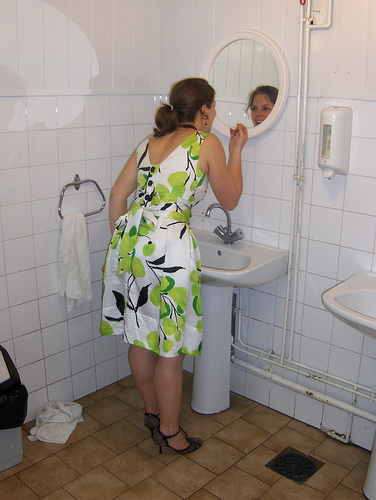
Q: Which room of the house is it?
A: It is a bathroom.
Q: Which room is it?
A: It is a bathroom.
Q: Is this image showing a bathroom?
A: Yes, it is showing a bathroom.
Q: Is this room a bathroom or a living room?
A: It is a bathroom.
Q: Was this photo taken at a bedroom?
A: No, the picture was taken in a bathroom.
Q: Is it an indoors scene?
A: Yes, it is indoors.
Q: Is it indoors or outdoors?
A: It is indoors.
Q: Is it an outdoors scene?
A: No, it is indoors.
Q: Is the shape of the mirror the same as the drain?
A: No, the mirror is round and the drain is square.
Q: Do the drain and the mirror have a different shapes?
A: Yes, the drain is round and the mirror is square.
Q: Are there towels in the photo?
A: Yes, there is a towel.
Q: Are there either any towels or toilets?
A: Yes, there is a towel.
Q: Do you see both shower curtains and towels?
A: No, there is a towel but no shower curtains.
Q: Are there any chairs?
A: No, there are no chairs.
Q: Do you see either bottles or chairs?
A: No, there are no chairs or bottles.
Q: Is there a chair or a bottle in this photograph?
A: No, there are no chairs or bottles.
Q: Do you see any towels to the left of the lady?
A: Yes, there is a towel to the left of the lady.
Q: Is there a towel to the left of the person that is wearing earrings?
A: Yes, there is a towel to the left of the lady.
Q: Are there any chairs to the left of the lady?
A: No, there is a towel to the left of the lady.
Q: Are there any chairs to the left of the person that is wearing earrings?
A: No, there is a towel to the left of the lady.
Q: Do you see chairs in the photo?
A: No, there are no chairs.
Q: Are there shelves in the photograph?
A: No, there are no shelves.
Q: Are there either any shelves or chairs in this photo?
A: No, there are no shelves or chairs.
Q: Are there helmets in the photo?
A: No, there are no helmets.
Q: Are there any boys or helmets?
A: No, there are no helmets or boys.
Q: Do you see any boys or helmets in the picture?
A: No, there are no helmets or boys.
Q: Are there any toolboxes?
A: No, there are no toolboxes.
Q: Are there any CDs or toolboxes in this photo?
A: No, there are no toolboxes or cds.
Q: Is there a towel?
A: Yes, there is a towel.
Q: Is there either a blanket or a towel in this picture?
A: Yes, there is a towel.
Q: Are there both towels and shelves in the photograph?
A: No, there is a towel but no shelves.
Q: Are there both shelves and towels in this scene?
A: No, there is a towel but no shelves.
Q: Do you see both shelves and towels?
A: No, there is a towel but no shelves.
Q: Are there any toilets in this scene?
A: No, there are no toilets.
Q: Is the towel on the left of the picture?
A: Yes, the towel is on the left of the image.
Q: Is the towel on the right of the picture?
A: No, the towel is on the left of the image.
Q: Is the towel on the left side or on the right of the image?
A: The towel is on the left of the image.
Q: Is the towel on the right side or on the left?
A: The towel is on the left of the image.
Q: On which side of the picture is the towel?
A: The towel is on the left of the image.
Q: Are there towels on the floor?
A: Yes, there is a towel on the floor.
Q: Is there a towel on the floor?
A: Yes, there is a towel on the floor.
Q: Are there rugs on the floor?
A: No, there is a towel on the floor.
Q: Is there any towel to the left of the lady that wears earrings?
A: Yes, there is a towel to the left of the lady.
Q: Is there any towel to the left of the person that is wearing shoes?
A: Yes, there is a towel to the left of the lady.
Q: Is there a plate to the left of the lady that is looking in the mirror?
A: No, there is a towel to the left of the lady.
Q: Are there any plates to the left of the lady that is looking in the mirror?
A: No, there is a towel to the left of the lady.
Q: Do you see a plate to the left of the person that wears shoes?
A: No, there is a towel to the left of the lady.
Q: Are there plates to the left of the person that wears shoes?
A: No, there is a towel to the left of the lady.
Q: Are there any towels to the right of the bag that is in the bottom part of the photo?
A: Yes, there is a towel to the right of the handbag.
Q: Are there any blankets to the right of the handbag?
A: No, there is a towel to the right of the handbag.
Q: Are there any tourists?
A: No, there are no tourists.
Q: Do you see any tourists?
A: No, there are no tourists.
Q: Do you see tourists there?
A: No, there are no tourists.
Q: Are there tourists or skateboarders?
A: No, there are no tourists or skateboarders.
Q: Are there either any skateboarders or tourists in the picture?
A: No, there are no tourists or skateboarders.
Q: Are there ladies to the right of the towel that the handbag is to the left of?
A: Yes, there is a lady to the right of the towel.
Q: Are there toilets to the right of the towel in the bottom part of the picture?
A: No, there is a lady to the right of the towel.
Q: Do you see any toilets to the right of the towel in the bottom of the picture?
A: No, there is a lady to the right of the towel.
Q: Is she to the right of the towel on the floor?
A: Yes, the lady is to the right of the towel.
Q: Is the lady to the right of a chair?
A: No, the lady is to the right of the towel.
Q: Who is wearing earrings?
A: The lady is wearing earrings.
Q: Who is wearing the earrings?
A: The lady is wearing earrings.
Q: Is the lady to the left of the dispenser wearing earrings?
A: Yes, the lady is wearing earrings.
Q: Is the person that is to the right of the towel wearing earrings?
A: Yes, the lady is wearing earrings.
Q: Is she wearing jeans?
A: No, the lady is wearing earrings.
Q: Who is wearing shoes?
A: The lady is wearing shoes.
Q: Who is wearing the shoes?
A: The lady is wearing shoes.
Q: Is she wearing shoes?
A: Yes, the lady is wearing shoes.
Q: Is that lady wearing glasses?
A: No, the lady is wearing shoes.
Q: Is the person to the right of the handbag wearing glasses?
A: No, the lady is wearing shoes.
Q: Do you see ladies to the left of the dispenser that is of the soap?
A: Yes, there is a lady to the left of the dispenser.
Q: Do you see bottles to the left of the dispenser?
A: No, there is a lady to the left of the dispenser.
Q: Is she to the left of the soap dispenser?
A: Yes, the lady is to the left of the dispenser.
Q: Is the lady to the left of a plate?
A: No, the lady is to the left of the dispenser.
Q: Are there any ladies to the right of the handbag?
A: Yes, there is a lady to the right of the handbag.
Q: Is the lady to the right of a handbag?
A: Yes, the lady is to the right of a handbag.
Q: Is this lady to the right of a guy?
A: No, the lady is to the right of a handbag.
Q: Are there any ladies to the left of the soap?
A: Yes, there is a lady to the left of the soap.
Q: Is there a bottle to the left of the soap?
A: No, there is a lady to the left of the soap.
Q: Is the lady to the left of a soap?
A: Yes, the lady is to the left of a soap.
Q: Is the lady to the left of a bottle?
A: No, the lady is to the left of a soap.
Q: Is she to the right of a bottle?
A: No, the lady is to the right of the towel.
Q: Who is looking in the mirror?
A: The lady is looking in the mirror.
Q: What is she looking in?
A: The lady is looking in the mirror.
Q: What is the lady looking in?
A: The lady is looking in the mirror.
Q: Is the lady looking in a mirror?
A: Yes, the lady is looking in a mirror.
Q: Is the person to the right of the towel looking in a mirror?
A: Yes, the lady is looking in a mirror.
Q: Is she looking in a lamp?
A: No, the lady is looking in a mirror.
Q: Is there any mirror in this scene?
A: Yes, there is a mirror.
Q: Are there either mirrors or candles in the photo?
A: Yes, there is a mirror.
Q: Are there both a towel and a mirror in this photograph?
A: Yes, there are both a mirror and a towel.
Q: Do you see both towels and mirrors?
A: Yes, there are both a mirror and a towel.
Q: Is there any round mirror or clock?
A: Yes, there is a round mirror.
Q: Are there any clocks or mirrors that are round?
A: Yes, the mirror is round.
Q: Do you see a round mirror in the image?
A: Yes, there is a round mirror.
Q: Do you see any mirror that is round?
A: Yes, there is a mirror that is round.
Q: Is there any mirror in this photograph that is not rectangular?
A: Yes, there is a round mirror.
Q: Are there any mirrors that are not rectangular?
A: Yes, there is a round mirror.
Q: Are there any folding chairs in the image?
A: No, there are no folding chairs.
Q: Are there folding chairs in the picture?
A: No, there are no folding chairs.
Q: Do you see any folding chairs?
A: No, there are no folding chairs.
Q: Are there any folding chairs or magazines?
A: No, there are no folding chairs or magazines.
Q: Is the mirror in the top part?
A: Yes, the mirror is in the top of the image.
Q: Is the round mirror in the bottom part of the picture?
A: No, the mirror is in the top of the image.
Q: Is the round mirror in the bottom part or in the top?
A: The mirror is in the top of the image.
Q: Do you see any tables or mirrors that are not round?
A: No, there is a mirror but it is round.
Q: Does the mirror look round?
A: Yes, the mirror is round.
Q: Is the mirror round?
A: Yes, the mirror is round.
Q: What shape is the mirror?
A: The mirror is round.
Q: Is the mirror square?
A: No, the mirror is round.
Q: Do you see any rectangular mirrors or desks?
A: No, there is a mirror but it is round.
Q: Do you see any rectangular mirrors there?
A: No, there is a mirror but it is round.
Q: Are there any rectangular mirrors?
A: No, there is a mirror but it is round.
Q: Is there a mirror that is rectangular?
A: No, there is a mirror but it is round.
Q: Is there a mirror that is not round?
A: No, there is a mirror but it is round.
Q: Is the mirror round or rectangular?
A: The mirror is round.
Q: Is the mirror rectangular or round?
A: The mirror is round.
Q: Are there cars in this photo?
A: No, there are no cars.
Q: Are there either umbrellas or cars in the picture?
A: No, there are no cars or umbrellas.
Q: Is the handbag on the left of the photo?
A: Yes, the handbag is on the left of the image.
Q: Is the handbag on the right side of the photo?
A: No, the handbag is on the left of the image.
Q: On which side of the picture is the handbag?
A: The handbag is on the left of the image.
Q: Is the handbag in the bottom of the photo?
A: Yes, the handbag is in the bottom of the image.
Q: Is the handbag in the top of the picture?
A: No, the handbag is in the bottom of the image.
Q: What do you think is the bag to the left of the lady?
A: The bag is a handbag.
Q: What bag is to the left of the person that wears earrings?
A: The bag is a handbag.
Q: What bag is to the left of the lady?
A: The bag is a handbag.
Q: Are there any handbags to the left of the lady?
A: Yes, there is a handbag to the left of the lady.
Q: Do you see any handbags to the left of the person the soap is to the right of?
A: Yes, there is a handbag to the left of the lady.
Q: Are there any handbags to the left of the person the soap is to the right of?
A: Yes, there is a handbag to the left of the lady.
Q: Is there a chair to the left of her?
A: No, there is a handbag to the left of the lady.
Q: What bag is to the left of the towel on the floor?
A: The bag is a handbag.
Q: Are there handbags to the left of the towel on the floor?
A: Yes, there is a handbag to the left of the towel.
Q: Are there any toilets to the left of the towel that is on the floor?
A: No, there is a handbag to the left of the towel.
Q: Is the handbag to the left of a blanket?
A: No, the handbag is to the left of a towel.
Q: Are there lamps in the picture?
A: No, there are no lamps.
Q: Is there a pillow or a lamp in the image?
A: No, there are no lamps or pillows.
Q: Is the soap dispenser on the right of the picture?
A: Yes, the dispenser is on the right of the image.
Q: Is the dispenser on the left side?
A: No, the dispenser is on the right of the image.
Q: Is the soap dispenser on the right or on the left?
A: The dispenser is on the right of the image.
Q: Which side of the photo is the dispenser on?
A: The dispenser is on the right of the image.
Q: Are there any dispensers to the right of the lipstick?
A: Yes, there is a dispenser to the right of the lipstick.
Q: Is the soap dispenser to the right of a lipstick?
A: Yes, the dispenser is to the right of a lipstick.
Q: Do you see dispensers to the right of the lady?
A: Yes, there is a dispenser to the right of the lady.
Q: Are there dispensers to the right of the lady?
A: Yes, there is a dispenser to the right of the lady.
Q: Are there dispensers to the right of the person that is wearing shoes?
A: Yes, there is a dispenser to the right of the lady.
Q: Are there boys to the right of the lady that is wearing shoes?
A: No, there is a dispenser to the right of the lady.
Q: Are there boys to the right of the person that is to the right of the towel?
A: No, there is a dispenser to the right of the lady.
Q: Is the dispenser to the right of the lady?
A: Yes, the dispenser is to the right of the lady.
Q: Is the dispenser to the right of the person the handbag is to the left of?
A: Yes, the dispenser is to the right of the lady.